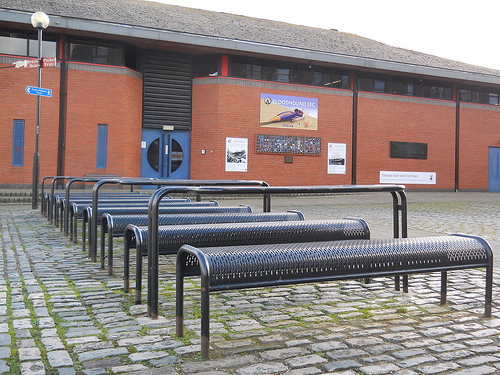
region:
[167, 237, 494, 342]
black bench on the ground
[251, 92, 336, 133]
sign on the wall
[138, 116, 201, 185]
blue door with windows.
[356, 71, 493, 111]
windows on top of building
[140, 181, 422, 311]
black bar beside benches.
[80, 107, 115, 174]
blue window on wall.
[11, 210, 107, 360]
brick stones on ground.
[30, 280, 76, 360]
grass in crevices of the brick stone.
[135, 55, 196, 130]
black wall above entrance way.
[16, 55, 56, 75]
post on a pole.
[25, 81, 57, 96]
blue direction sign on a black pole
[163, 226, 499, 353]
black metal bench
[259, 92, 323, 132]
multicolored BloodHound graphic sign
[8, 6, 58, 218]
lamp post with two signs on it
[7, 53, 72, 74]
red direction sign on the black post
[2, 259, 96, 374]
ground composed of cobblestone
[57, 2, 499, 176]
large brown building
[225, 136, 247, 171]
black and white sign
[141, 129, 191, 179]
blue door with a circular design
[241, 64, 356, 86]
windows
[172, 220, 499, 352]
black metal open work bench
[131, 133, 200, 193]
blue doors with semi-circular windows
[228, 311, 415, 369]
gray rectangular stone pavers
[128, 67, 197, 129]
black ridged design on brick building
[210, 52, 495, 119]
row of windows high up on brick building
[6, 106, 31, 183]
blue rectangular shape set into brick building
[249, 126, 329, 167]
rectangle mosaic on side of brick building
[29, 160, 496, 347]
row of shiny black benches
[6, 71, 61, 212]
light blue sign atop black post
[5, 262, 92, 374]
rectangular pavers with grass growing in between them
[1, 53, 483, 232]
a tall brick building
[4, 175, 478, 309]
a row of black benches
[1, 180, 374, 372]
a brick lot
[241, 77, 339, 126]
a sign on the side of a building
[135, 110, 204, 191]
a blue door with windows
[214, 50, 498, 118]
windows at the top of building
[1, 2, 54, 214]
a tall light pole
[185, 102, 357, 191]
several signs on building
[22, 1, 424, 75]
black roof of a building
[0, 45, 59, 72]
a red sign with a hand pointing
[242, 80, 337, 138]
poster on a red brick wall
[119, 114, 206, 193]
blue doors with semicircle windows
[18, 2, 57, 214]
metal street light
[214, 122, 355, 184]
white posters on a brick wall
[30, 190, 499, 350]
benches on a mossy brick sidewalk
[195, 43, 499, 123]
row of windows at the top of a building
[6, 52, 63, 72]
red street sign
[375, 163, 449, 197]
wide white poster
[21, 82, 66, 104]
blue street sign with white lettering